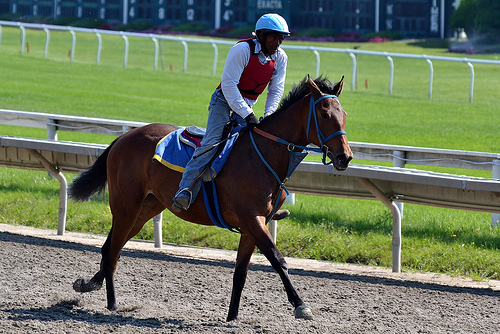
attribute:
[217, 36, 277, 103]
vest — red, black, existing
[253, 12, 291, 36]
helmet — white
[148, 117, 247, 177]
saddle — blue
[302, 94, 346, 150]
bridle — blue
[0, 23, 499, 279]
grass — green, in field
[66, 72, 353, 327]
horse — brown, racing, running, existing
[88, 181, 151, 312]
leg — existing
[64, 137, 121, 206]
tail — black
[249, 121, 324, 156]
reins — blue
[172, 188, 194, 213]
stirrup — for riding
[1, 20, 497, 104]
guard rail — white, existing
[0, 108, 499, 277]
fence — white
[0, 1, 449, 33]
wall — existing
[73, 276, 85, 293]
hoof — existing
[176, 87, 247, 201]
jeans — existing